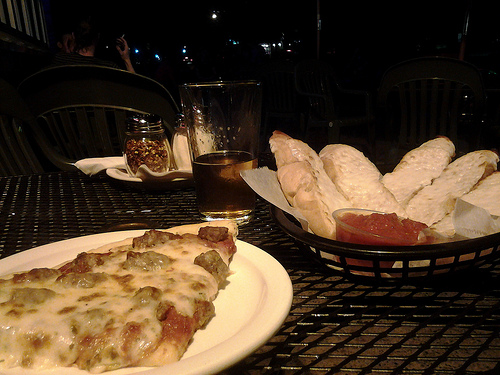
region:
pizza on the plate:
[20, 246, 237, 365]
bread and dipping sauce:
[281, 110, 476, 239]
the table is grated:
[287, 308, 364, 360]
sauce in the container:
[342, 210, 436, 240]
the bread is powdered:
[381, 166, 448, 213]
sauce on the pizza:
[11, 270, 188, 339]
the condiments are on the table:
[110, 105, 239, 177]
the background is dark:
[134, 11, 329, 91]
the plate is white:
[253, 300, 290, 339]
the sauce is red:
[372, 220, 404, 239]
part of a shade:
[371, 281, 410, 331]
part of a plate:
[227, 310, 238, 330]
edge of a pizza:
[181, 330, 199, 346]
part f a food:
[160, 286, 180, 312]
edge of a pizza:
[172, 274, 187, 294]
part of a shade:
[347, 264, 403, 349]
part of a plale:
[228, 287, 245, 319]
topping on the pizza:
[147, 286, 172, 302]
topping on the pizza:
[80, 288, 98, 309]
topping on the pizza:
[180, 271, 214, 293]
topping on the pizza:
[75, 303, 101, 320]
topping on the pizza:
[187, 249, 220, 270]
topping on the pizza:
[32, 285, 67, 303]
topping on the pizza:
[131, 258, 156, 273]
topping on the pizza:
[81, 265, 105, 280]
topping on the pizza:
[88, 287, 110, 310]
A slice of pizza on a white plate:
[0, 216, 238, 366]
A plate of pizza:
[2, 218, 294, 370]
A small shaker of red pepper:
[122, 111, 172, 178]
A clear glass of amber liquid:
[178, 78, 263, 224]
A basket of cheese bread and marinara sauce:
[265, 130, 497, 287]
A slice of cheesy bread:
[270, 132, 345, 235]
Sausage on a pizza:
[0, 218, 240, 368]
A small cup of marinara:
[329, 206, 434, 272]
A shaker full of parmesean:
[171, 108, 193, 175]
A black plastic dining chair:
[288, 53, 373, 143]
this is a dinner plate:
[19, 199, 311, 372]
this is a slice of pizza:
[0, 187, 271, 364]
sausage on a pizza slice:
[35, 242, 233, 355]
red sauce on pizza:
[112, 288, 200, 365]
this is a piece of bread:
[408, 142, 485, 250]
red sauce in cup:
[317, 197, 431, 264]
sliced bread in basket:
[202, 135, 494, 293]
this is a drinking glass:
[150, 79, 297, 225]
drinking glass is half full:
[165, 125, 280, 215]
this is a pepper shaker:
[115, 96, 182, 193]